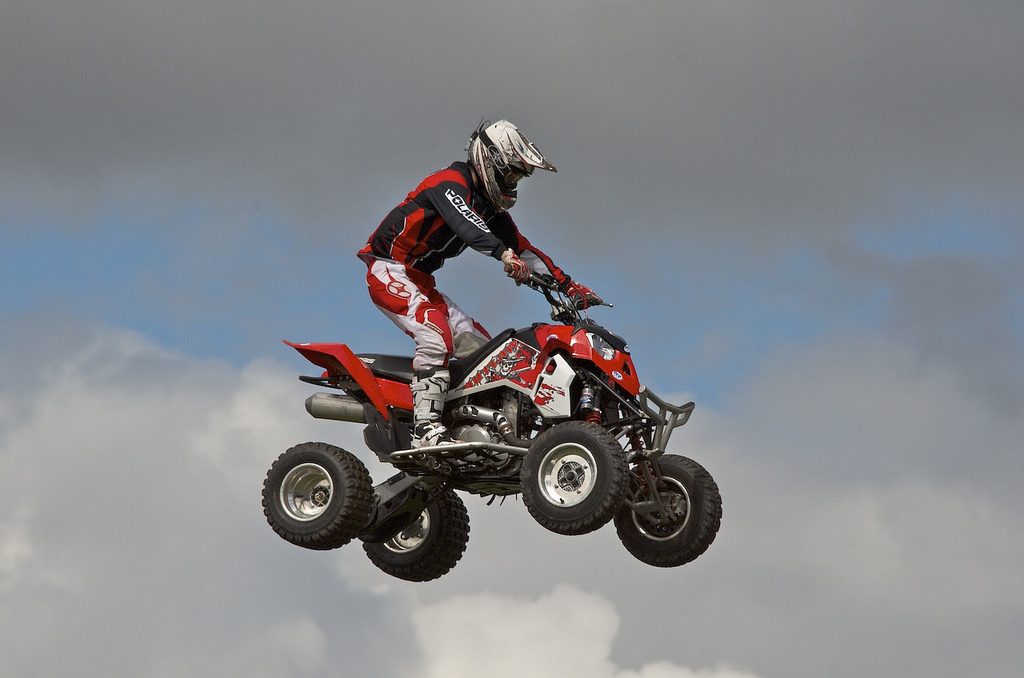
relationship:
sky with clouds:
[66, 144, 1022, 594] [66, 144, 1022, 594]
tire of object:
[614, 454, 723, 568] [261, 265, 721, 582]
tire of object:
[520, 421, 630, 537] [261, 265, 721, 582]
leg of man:
[367, 257, 459, 448] [367, 121, 555, 448]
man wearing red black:
[354, 117, 601, 448] [399, 187, 523, 258]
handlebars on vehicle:
[494, 259, 613, 326] [272, 316, 718, 567]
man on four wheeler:
[354, 117, 601, 448] [295, 333, 716, 572]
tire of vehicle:
[258, 442, 364, 548] [272, 316, 718, 567]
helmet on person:
[472, 116, 539, 219] [371, 114, 555, 447]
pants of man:
[359, 262, 480, 458] [354, 117, 601, 448]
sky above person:
[0, 201, 1021, 410] [371, 114, 555, 447]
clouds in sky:
[73, 32, 741, 137] [10, 12, 1013, 671]